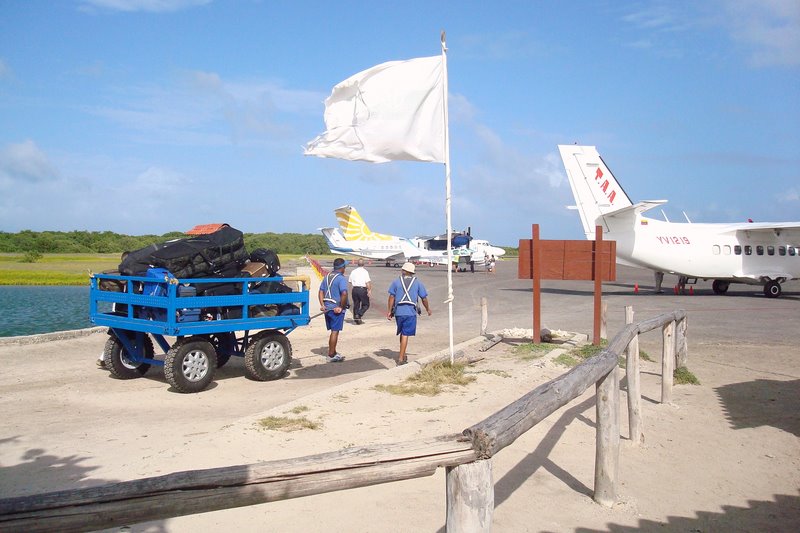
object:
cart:
[89, 273, 308, 336]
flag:
[304, 36, 454, 363]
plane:
[559, 144, 797, 296]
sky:
[2, 0, 798, 244]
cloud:
[5, 137, 62, 182]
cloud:
[453, 93, 573, 225]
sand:
[251, 331, 599, 433]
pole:
[439, 32, 455, 368]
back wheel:
[164, 337, 218, 393]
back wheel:
[104, 333, 155, 379]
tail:
[557, 145, 636, 248]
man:
[385, 262, 433, 366]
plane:
[322, 205, 505, 272]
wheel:
[245, 330, 291, 381]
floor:
[0, 262, 796, 533]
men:
[350, 259, 371, 324]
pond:
[0, 285, 85, 324]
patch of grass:
[430, 366, 454, 380]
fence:
[2, 315, 691, 532]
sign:
[518, 225, 614, 345]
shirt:
[391, 277, 428, 316]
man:
[321, 258, 349, 361]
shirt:
[321, 273, 348, 310]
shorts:
[396, 315, 416, 336]